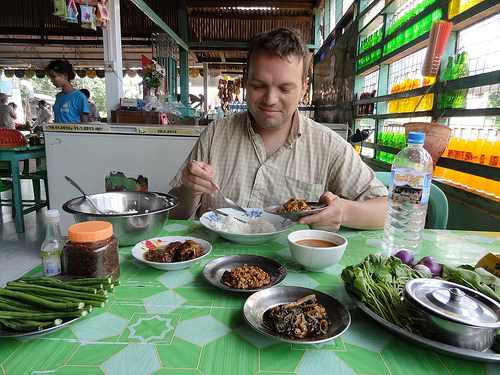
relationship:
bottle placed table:
[381, 131, 433, 253] [3, 229, 498, 373]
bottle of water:
[381, 131, 433, 253] [383, 171, 433, 258]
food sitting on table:
[148, 215, 337, 344] [6, 192, 433, 339]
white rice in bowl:
[208, 211, 277, 233] [198, 208, 299, 246]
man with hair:
[163, 27, 388, 235] [245, 27, 307, 86]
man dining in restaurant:
[204, 14, 380, 222] [2, 4, 496, 373]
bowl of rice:
[64, 187, 174, 244] [204, 212, 276, 234]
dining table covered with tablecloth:
[1, 218, 497, 371] [157, 322, 229, 348]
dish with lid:
[404, 271, 499, 356] [403, 269, 499, 332]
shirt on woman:
[50, 88, 90, 125] [43, 55, 91, 123]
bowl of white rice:
[171, 163, 319, 245] [208, 211, 277, 233]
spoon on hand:
[188, 157, 246, 214] [178, 157, 218, 196]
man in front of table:
[163, 27, 388, 235] [38, 216, 498, 371]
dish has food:
[127, 222, 216, 268] [143, 213, 340, 340]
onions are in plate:
[394, 253, 442, 277] [352, 291, 500, 356]